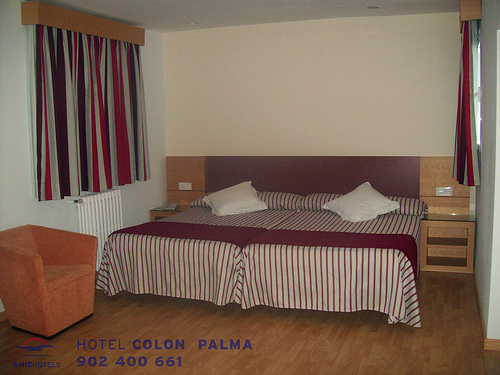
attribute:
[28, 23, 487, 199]
curtains — striped, red, brown, white, multi-colored, burgundy, gray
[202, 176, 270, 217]
pillow — white, square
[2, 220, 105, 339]
chair — orange, small, unattractive, brown, club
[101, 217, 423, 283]
blanket — folded, maroon, red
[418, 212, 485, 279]
table — wooden, wood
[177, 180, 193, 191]
receptor — electrical, white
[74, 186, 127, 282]
radiator — white, heater, heating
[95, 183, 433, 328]
sheets — striped, red, white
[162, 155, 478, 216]
headboard — maroon, wooden, red, wood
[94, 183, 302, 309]
bed — pushed, average sized, full, pulled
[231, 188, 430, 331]
bed — pushed, average sized, full, pulled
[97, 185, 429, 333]
bedspread — striped, red, white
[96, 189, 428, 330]
stripes — red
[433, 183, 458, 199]
outlet — electrical, white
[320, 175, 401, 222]
pillow — white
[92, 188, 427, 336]
comforter — striped, red, white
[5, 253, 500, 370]
floors — shiny, wooden, clean, wood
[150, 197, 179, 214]
phone — silver, home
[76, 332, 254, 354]
name — hotel colon palma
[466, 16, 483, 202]
light — coming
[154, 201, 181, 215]
telephone — sitting